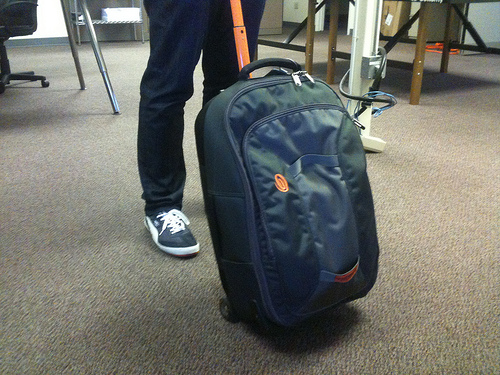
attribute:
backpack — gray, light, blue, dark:
[202, 54, 385, 327]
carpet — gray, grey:
[7, 133, 145, 351]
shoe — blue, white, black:
[140, 214, 201, 257]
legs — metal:
[394, 3, 434, 115]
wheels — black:
[217, 300, 234, 320]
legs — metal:
[77, 0, 124, 116]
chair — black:
[0, 0, 51, 91]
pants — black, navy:
[141, 1, 201, 221]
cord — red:
[428, 39, 444, 60]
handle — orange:
[228, 1, 253, 79]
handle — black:
[239, 54, 309, 81]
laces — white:
[159, 210, 189, 234]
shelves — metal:
[77, 9, 145, 40]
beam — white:
[345, 0, 388, 108]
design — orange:
[273, 173, 291, 195]